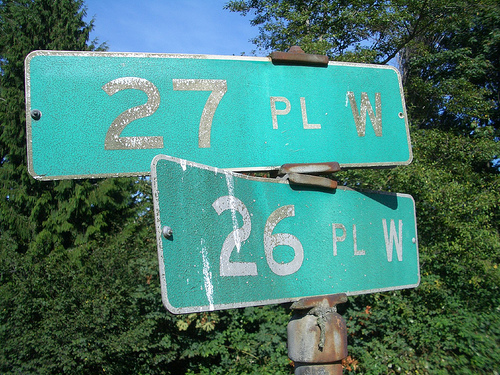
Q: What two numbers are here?
A: 27 and 26.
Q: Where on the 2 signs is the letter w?
A: The right side.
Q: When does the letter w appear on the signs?
A: At the end.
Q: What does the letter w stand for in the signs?
A: West.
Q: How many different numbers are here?
A: 2.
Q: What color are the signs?
A: Green.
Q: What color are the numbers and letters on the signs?
A: White.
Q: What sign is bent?
A: 26 pl w.